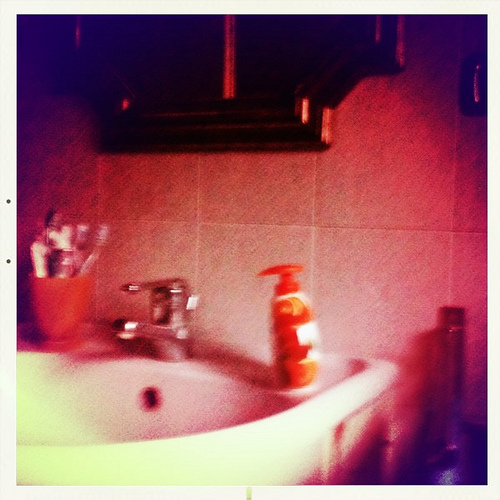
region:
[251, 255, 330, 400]
soap on the sink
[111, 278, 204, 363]
silver faucet on the white sink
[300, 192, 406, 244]
lines in the tile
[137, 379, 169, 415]
emergency drain hole in the sink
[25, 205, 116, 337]
cup of toothbrushes on the sink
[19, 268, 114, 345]
red toothbrush holder on the sink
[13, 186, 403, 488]
white bathroom sink with tile wall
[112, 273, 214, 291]
hot and cold water handle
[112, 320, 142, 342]
tip of the water faucet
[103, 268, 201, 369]
silver bathroom faucet on the sink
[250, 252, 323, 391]
plastic bottle of soap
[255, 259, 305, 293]
plastic spout on the soap bottle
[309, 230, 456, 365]
white ceramic tile on the wall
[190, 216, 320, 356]
white ceramic tile on the wall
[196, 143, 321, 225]
white ceramic tile on the wall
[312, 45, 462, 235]
white ceramic tile on the wall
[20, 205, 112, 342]
red cup filled with toothbrushes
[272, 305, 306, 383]
A soap dispenser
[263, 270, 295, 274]
The spout of the dispenser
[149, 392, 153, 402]
A hole in the sink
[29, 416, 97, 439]
The inside of the basin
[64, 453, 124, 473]
The outside of the basin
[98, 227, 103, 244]
The bristles of a tooth brush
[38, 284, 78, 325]
A cup on the wash basin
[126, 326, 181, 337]
A metallic tap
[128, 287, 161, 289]
The tap handle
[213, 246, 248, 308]
A tile on the sink wall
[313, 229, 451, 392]
white tile on wall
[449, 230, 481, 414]
white tile on wall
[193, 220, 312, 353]
white tile on wall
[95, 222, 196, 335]
white tile on wall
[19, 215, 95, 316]
white tile on wall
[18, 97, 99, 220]
white tile on wall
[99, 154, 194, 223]
white tile on wall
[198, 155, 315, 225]
white tile on wall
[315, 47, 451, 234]
white tile on wall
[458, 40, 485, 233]
white tile on wall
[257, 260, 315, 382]
bottle of soap on edge of sink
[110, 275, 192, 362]
a chrome faucet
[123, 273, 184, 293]
the faucet handle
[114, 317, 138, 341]
the spout of the bathroom faucet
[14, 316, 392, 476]
a white sink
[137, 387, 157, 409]
small drain hole at the back of the sink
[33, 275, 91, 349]
a red cup to the left of the faucet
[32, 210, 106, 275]
toothbrushes and toothpaste in the red cup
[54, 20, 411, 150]
mirror above the sink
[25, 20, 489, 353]
tile wall above the sink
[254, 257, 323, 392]
container of soap stands on sink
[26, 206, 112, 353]
container holds toothbrushes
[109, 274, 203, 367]
faucet is turned off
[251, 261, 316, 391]
a white and orange colored soap dispenser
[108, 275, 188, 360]
a silver colored water faucet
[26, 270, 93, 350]
an orange colored cup